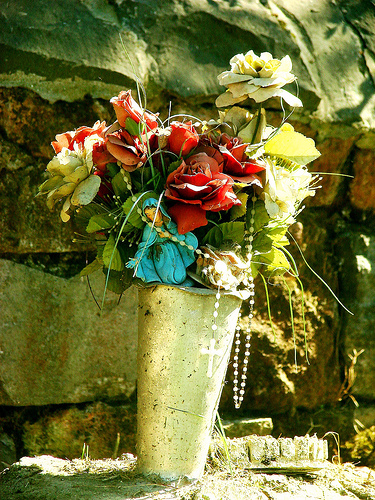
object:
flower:
[264, 164, 311, 217]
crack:
[1, 250, 96, 279]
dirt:
[251, 434, 329, 474]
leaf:
[86, 216, 120, 234]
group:
[36, 48, 351, 409]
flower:
[164, 120, 267, 237]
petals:
[266, 122, 321, 165]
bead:
[235, 340, 240, 345]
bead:
[234, 356, 238, 360]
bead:
[234, 371, 239, 376]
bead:
[233, 387, 238, 392]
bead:
[235, 404, 240, 409]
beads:
[204, 253, 210, 259]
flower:
[34, 141, 102, 223]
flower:
[50, 120, 118, 201]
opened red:
[163, 152, 240, 233]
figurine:
[125, 198, 199, 287]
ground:
[0, 438, 373, 500]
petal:
[167, 202, 208, 234]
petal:
[219, 145, 243, 175]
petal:
[243, 162, 266, 175]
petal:
[180, 172, 210, 186]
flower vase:
[135, 276, 242, 484]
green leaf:
[102, 234, 124, 271]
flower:
[105, 88, 160, 172]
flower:
[215, 49, 303, 108]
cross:
[201, 338, 223, 377]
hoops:
[141, 151, 179, 195]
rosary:
[117, 113, 257, 409]